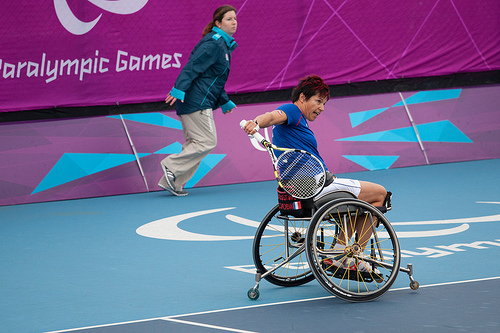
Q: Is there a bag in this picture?
A: No, there are no bags.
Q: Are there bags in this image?
A: No, there are no bags.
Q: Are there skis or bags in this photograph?
A: No, there are no bags or skis.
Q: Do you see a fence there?
A: No, there are no fences.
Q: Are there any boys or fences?
A: No, there are no fences or boys.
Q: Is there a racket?
A: Yes, there is a racket.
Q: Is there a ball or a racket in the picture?
A: Yes, there is a racket.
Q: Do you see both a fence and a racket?
A: No, there is a racket but no fences.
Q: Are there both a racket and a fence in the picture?
A: No, there is a racket but no fences.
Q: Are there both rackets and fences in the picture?
A: No, there is a racket but no fences.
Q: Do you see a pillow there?
A: No, there are no pillows.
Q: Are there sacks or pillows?
A: No, there are no pillows or sacks.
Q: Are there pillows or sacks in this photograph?
A: No, there are no pillows or sacks.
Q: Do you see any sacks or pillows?
A: No, there are no pillows or sacks.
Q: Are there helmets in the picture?
A: No, there are no helmets.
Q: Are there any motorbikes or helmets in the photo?
A: No, there are no helmets or motorbikes.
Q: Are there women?
A: Yes, there is a woman.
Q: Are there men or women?
A: Yes, there is a woman.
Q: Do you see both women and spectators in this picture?
A: No, there is a woman but no spectators.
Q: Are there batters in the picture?
A: No, there are no batters.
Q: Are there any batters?
A: No, there are no batters.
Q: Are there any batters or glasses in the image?
A: No, there are no batters or glasses.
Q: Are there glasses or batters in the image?
A: No, there are no batters or glasses.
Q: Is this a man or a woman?
A: This is a woman.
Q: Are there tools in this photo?
A: No, there are no tools.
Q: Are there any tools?
A: No, there are no tools.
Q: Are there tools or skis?
A: No, there are no tools or skis.